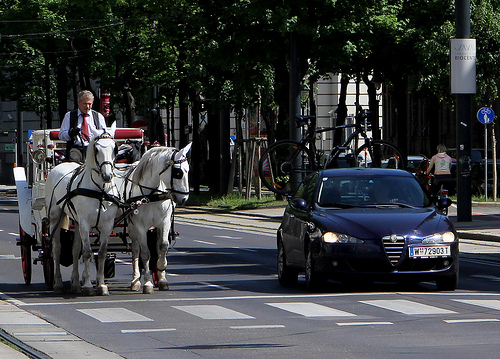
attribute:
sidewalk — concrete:
[3, 297, 123, 357]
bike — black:
[251, 97, 358, 163]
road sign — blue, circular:
[476, 113, 484, 124]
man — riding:
[45, 92, 103, 168]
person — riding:
[420, 145, 453, 177]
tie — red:
[65, 107, 100, 137]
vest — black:
[54, 117, 126, 168]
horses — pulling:
[58, 150, 209, 272]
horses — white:
[40, 137, 204, 281]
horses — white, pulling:
[54, 142, 196, 234]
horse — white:
[48, 140, 138, 259]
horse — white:
[75, 126, 191, 269]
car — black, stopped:
[263, 167, 467, 306]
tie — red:
[77, 103, 105, 139]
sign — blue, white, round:
[461, 110, 493, 129]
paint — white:
[12, 283, 496, 355]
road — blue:
[0, 192, 487, 356]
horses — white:
[34, 134, 197, 296]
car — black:
[274, 163, 466, 286]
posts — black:
[442, 0, 476, 225]